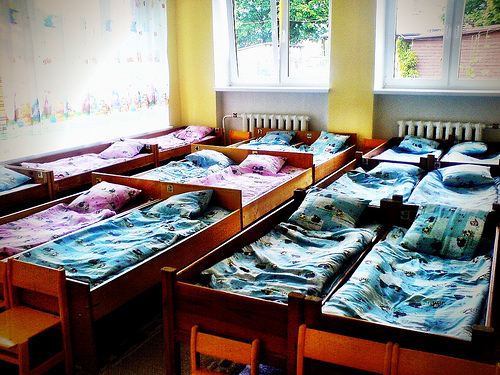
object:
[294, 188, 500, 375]
beds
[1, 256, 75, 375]
chair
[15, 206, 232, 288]
sheet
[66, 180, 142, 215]
pillow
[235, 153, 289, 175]
pillow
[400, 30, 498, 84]
wall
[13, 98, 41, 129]
drawing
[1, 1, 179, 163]
wall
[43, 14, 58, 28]
drawing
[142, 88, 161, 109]
drawing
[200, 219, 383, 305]
sheet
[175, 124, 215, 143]
pillow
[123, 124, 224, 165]
bed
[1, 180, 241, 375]
bed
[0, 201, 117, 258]
sheet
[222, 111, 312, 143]
radiator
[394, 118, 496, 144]
radiator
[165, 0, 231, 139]
wall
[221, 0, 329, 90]
window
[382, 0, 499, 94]
window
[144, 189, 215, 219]
pillow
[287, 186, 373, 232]
pillow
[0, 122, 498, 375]
group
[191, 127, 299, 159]
bed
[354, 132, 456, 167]
bed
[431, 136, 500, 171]
bed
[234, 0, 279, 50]
trees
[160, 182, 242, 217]
headboard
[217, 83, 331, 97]
window sill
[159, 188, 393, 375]
bed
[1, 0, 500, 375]
room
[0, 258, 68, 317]
back rest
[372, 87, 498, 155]
wall